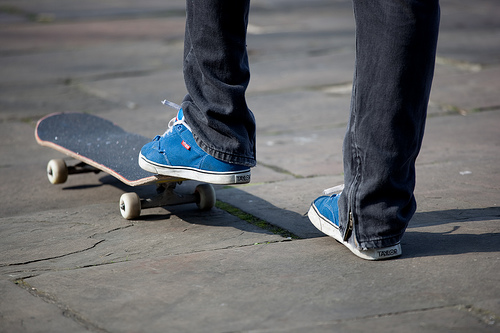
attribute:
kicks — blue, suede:
[137, 107, 407, 272]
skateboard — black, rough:
[24, 103, 219, 231]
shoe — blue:
[128, 98, 255, 195]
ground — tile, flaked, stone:
[1, 1, 499, 331]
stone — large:
[6, 218, 496, 332]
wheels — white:
[45, 156, 226, 240]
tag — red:
[175, 138, 197, 157]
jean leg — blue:
[330, 0, 438, 253]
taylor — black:
[370, 242, 403, 258]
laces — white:
[157, 92, 360, 207]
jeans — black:
[182, 0, 437, 260]